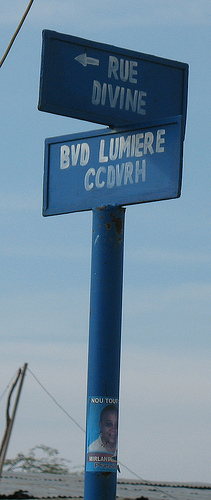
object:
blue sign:
[39, 135, 184, 203]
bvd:
[53, 143, 94, 170]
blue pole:
[86, 206, 131, 492]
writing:
[95, 132, 168, 161]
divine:
[90, 79, 146, 116]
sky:
[1, 1, 209, 481]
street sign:
[34, 29, 187, 132]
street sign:
[41, 113, 186, 216]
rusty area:
[95, 204, 124, 242]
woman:
[97, 404, 119, 451]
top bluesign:
[39, 30, 189, 139]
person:
[97, 405, 120, 455]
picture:
[85, 395, 119, 471]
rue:
[106, 53, 145, 87]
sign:
[34, 21, 191, 142]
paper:
[87, 393, 122, 470]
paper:
[86, 393, 121, 475]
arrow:
[75, 52, 100, 66]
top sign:
[37, 28, 187, 138]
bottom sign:
[42, 114, 183, 216]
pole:
[80, 204, 126, 499]